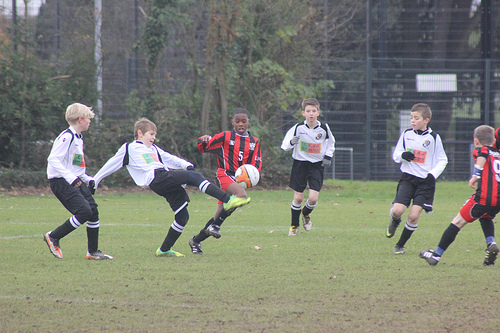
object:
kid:
[85, 116, 253, 260]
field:
[0, 181, 500, 332]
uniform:
[84, 140, 211, 228]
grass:
[0, 177, 499, 332]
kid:
[41, 100, 117, 260]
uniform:
[45, 124, 102, 224]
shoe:
[222, 193, 251, 214]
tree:
[201, 0, 335, 189]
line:
[0, 220, 389, 232]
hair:
[64, 102, 97, 126]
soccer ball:
[233, 163, 261, 189]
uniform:
[196, 129, 264, 204]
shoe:
[154, 247, 186, 258]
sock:
[85, 220, 102, 252]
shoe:
[418, 249, 442, 267]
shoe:
[84, 250, 114, 261]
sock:
[49, 217, 81, 247]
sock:
[432, 222, 463, 256]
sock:
[479, 219, 496, 246]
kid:
[186, 107, 264, 257]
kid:
[279, 96, 337, 238]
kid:
[382, 100, 447, 257]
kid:
[417, 122, 500, 267]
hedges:
[0, 168, 49, 192]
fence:
[0, 0, 500, 181]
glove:
[290, 135, 301, 145]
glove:
[401, 151, 417, 163]